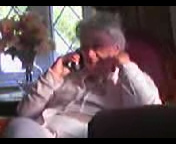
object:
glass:
[53, 5, 81, 68]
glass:
[16, 54, 58, 95]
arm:
[87, 104, 175, 138]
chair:
[69, 35, 176, 137]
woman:
[3, 10, 162, 140]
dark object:
[88, 105, 176, 137]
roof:
[70, 46, 82, 74]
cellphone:
[66, 47, 87, 71]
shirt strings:
[70, 70, 100, 123]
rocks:
[18, 81, 35, 87]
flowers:
[0, 11, 56, 68]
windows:
[0, 5, 83, 87]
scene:
[0, 5, 171, 138]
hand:
[50, 48, 85, 75]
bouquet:
[0, 10, 55, 81]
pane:
[0, 5, 12, 23]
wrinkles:
[25, 68, 53, 104]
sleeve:
[16, 65, 65, 118]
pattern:
[53, 5, 80, 48]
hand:
[110, 50, 130, 68]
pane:
[53, 5, 80, 55]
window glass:
[0, 6, 83, 80]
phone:
[71, 49, 84, 71]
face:
[81, 26, 117, 76]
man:
[1, 13, 161, 138]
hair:
[74, 15, 127, 51]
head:
[74, 15, 126, 77]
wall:
[1, 0, 174, 138]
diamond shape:
[53, 6, 81, 53]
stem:
[24, 67, 32, 82]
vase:
[16, 80, 40, 96]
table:
[0, 87, 37, 117]